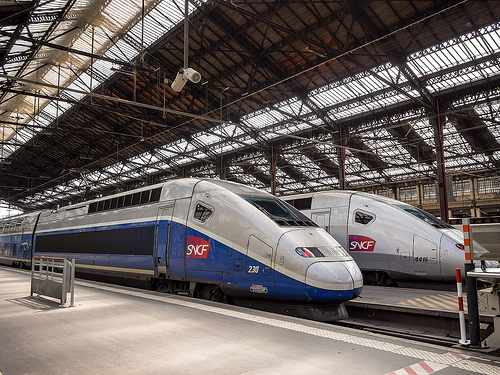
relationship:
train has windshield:
[1, 173, 367, 329] [240, 193, 324, 231]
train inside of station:
[1, 173, 367, 329] [1, 1, 499, 374]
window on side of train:
[148, 187, 162, 205] [1, 173, 367, 329]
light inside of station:
[167, 65, 206, 96] [1, 1, 499, 374]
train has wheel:
[1, 173, 367, 329] [151, 277, 224, 302]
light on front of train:
[296, 243, 353, 261] [1, 173, 367, 329]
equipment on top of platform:
[29, 251, 79, 312] [2, 266, 499, 373]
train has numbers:
[1, 173, 367, 329] [245, 259, 264, 277]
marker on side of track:
[451, 265, 476, 350] [322, 298, 499, 361]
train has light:
[1, 173, 367, 329] [296, 243, 353, 261]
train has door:
[1, 173, 367, 329] [151, 202, 175, 280]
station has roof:
[1, 1, 499, 374] [2, 1, 500, 215]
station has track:
[1, 1, 499, 374] [322, 298, 499, 361]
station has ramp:
[1, 1, 499, 374] [345, 280, 499, 325]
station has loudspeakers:
[1, 1, 499, 374] [166, 64, 207, 99]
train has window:
[1, 173, 367, 329] [148, 187, 162, 205]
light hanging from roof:
[167, 65, 206, 96] [2, 1, 500, 215]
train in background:
[277, 189, 497, 290] [5, 121, 497, 266]